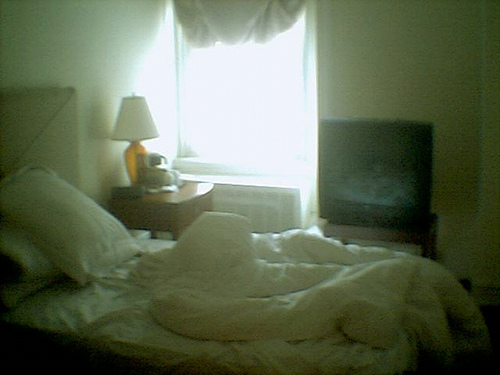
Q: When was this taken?
A: Daytime inside.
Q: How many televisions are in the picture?
A: One.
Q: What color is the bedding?
A: White.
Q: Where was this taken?
A: In a bedroom.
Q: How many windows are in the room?
A: One.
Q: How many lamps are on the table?
A: One.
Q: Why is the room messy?
A: The bed is unmade.